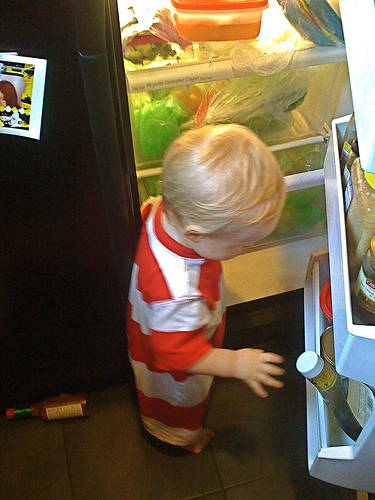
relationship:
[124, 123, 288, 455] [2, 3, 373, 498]
boy looking in fridge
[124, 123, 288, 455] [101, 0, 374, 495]
boy looking in fridge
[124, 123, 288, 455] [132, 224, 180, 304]
boy wearing stripe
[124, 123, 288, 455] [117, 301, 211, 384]
boy wearing stripe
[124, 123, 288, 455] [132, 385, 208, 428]
boy wearing stripe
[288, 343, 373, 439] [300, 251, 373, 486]
bottle on refrigerator shelf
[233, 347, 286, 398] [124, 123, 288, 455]
hand of boy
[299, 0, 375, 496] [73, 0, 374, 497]
door of refrigerator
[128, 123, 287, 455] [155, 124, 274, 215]
boy has hair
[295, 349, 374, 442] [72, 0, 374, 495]
bottle in fridge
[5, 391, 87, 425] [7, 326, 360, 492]
bottle on floor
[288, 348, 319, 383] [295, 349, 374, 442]
cap on bottle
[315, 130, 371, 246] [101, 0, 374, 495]
door of fridge